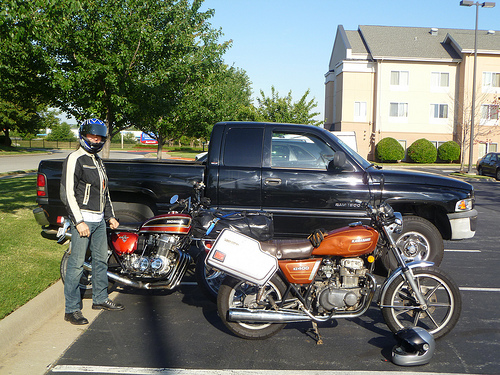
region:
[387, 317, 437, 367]
Helmet is on the ground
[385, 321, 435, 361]
Silver and black helmet on ground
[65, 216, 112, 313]
Man is wearing jeans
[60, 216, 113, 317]
Man is wearing blue jeans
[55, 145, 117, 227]
Man is wearing a jacket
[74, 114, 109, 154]
Man is wearing a helmet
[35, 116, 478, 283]
Truck is parked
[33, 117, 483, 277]
Black truck is parked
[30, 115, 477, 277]
Pickup truck is parked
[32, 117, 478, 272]
Black pickup truck is parked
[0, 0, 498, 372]
A parking lot scene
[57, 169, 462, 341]
Motorcycles are parked on the lot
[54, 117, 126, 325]
A man is standing beside the motorcycle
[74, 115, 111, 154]
The man is wearing a helmet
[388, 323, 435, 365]
A helmet is on the ground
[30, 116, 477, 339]
A truck is parked beside the motorcycles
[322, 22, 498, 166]
A building is in the background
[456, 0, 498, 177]
A street light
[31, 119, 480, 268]
The truck is black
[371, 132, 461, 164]
Bushes are in front of the building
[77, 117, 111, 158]
Person is wearing a helmet.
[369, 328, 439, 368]
Helmet on the ground.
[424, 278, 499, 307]
Line on the parking lot.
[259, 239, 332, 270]
The seat is brown.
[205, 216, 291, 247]
Bag on the bike.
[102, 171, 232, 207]
The truck is black.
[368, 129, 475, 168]
The shrubs by the building.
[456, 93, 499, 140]
No leaves on the tree.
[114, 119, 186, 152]
Car in the background.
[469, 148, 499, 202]
Car on the side.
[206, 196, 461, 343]
an orange motorcycle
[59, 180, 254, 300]
a black and red motorcycle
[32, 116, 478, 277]
a black pick up truck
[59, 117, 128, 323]
a man standing in parking lot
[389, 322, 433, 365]
a silver and black helmet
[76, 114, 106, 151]
a black motorcycle helmet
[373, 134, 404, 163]
a trimmed green bush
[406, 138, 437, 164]
a trimmed green bush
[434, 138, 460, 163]
a trimmed green bush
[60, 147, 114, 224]
a black and white motorcycle jacket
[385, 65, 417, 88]
the window of a building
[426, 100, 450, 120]
the opened window of a building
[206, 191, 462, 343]
a motorcycle parked in a parking lot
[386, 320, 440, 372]
a grey motorcycle helmet on the pavement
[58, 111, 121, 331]
a person wearing a motorcycle helmet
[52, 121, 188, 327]
a person standing by a motorcycle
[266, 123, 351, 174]
the window of a truck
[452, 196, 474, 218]
the headlight of a truck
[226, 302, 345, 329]
the exhaust pipe of a motorcycle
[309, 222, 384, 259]
the gas tank of a motorcycle